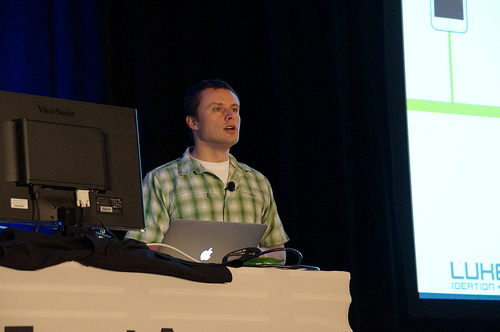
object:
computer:
[387, 0, 500, 320]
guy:
[125, 79, 290, 265]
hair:
[183, 79, 237, 142]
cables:
[222, 246, 321, 271]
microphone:
[228, 181, 235, 191]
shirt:
[124, 146, 290, 247]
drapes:
[1, 0, 109, 236]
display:
[401, 0, 500, 300]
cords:
[145, 243, 200, 263]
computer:
[0, 90, 145, 236]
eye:
[213, 107, 220, 112]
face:
[198, 88, 241, 143]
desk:
[0, 266, 352, 332]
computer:
[155, 219, 268, 264]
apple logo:
[199, 247, 214, 260]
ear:
[186, 115, 198, 131]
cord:
[35, 192, 118, 240]